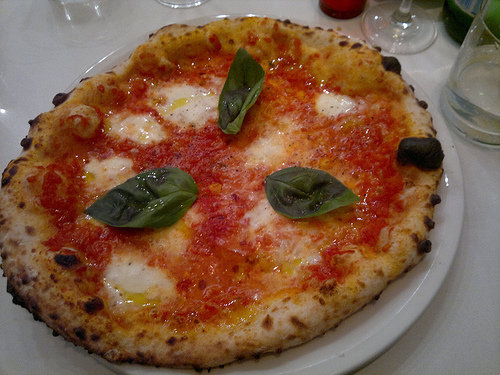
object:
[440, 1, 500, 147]
glass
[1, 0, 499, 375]
table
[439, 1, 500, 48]
bottle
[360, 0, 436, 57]
wine glass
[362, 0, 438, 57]
stem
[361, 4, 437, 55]
base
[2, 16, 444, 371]
pizza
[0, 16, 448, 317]
cheese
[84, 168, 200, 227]
spinach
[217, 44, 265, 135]
spinach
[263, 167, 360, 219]
spinach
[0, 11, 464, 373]
plate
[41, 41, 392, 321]
sauce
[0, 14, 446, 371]
crust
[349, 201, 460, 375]
shadow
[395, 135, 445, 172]
spot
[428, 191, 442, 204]
spot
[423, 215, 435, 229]
spot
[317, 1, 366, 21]
cup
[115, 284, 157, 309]
grease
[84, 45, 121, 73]
glare